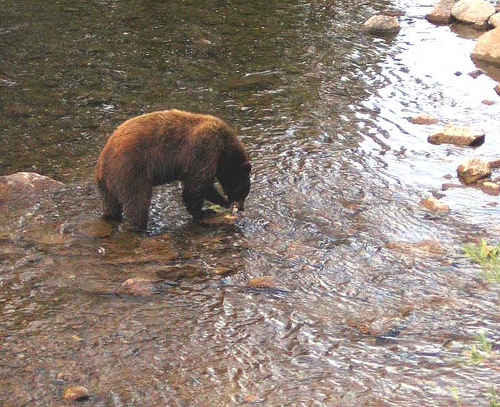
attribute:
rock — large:
[448, 1, 496, 29]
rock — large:
[466, 28, 499, 67]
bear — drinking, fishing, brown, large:
[87, 105, 257, 243]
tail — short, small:
[95, 158, 107, 188]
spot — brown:
[384, 289, 454, 317]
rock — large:
[4, 165, 64, 213]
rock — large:
[422, 3, 458, 27]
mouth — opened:
[229, 198, 244, 218]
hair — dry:
[88, 107, 197, 177]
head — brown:
[216, 161, 254, 213]